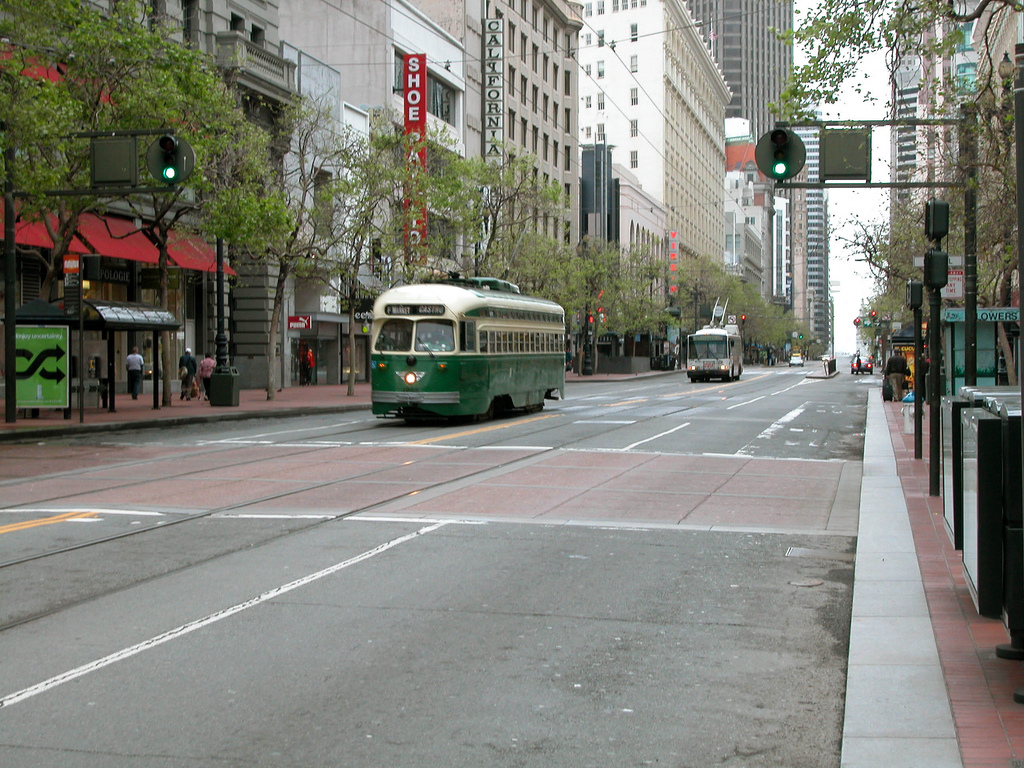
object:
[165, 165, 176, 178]
light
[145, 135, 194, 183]
traffic signal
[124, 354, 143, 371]
shirt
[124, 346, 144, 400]
person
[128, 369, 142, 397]
pants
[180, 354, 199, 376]
shirt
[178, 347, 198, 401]
person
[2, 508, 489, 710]
line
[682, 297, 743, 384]
bus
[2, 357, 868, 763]
road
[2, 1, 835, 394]
buildings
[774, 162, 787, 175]
street light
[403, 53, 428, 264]
sign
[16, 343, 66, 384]
arrow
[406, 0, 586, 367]
building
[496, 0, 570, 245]
windows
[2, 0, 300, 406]
tree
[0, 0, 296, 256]
leaves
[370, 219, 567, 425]
bus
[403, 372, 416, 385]
light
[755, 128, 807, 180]
traffic light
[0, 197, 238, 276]
awning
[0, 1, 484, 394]
building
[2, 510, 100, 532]
line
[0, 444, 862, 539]
crosswalk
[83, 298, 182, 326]
canopy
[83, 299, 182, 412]
bus stop